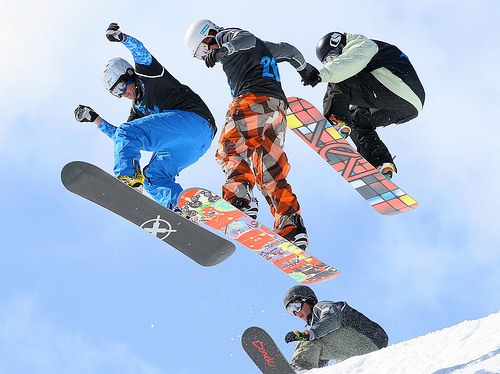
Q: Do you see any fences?
A: No, there are no fences.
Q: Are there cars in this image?
A: No, there are no cars.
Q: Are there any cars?
A: No, there are no cars.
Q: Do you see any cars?
A: No, there are no cars.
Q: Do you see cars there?
A: No, there are no cars.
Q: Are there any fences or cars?
A: No, there are no cars or fences.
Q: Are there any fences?
A: No, there are no fences.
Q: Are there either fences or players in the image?
A: No, there are no fences or players.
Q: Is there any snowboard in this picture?
A: Yes, there is a snowboard.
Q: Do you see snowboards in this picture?
A: Yes, there is a snowboard.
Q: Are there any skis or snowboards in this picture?
A: Yes, there is a snowboard.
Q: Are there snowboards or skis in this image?
A: Yes, there is a snowboard.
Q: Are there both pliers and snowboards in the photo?
A: No, there is a snowboard but no pliers.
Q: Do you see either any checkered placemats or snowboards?
A: Yes, there is a checkered snowboard.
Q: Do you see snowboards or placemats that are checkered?
A: Yes, the snowboard is checkered.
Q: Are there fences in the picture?
A: No, there are no fences.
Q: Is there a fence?
A: No, there are no fences.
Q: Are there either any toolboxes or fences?
A: No, there are no fences or toolboxes.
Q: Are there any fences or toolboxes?
A: No, there are no fences or toolboxes.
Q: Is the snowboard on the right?
A: Yes, the snowboard is on the right of the image.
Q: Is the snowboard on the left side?
A: No, the snowboard is on the right of the image.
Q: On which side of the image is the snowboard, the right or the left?
A: The snowboard is on the right of the image.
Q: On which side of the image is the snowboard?
A: The snowboard is on the right of the image.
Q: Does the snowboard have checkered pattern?
A: Yes, the snowboard is checkered.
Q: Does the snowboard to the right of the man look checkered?
A: Yes, the snowboard is checkered.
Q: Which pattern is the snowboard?
A: The snowboard is checkered.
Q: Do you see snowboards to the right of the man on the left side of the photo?
A: Yes, there is a snowboard to the right of the man.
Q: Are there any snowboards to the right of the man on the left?
A: Yes, there is a snowboard to the right of the man.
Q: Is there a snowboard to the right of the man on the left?
A: Yes, there is a snowboard to the right of the man.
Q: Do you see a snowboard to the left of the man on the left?
A: No, the snowboard is to the right of the man.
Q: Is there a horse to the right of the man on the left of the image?
A: No, there is a snowboard to the right of the man.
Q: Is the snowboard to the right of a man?
A: Yes, the snowboard is to the right of a man.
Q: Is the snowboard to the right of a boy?
A: No, the snowboard is to the right of a man.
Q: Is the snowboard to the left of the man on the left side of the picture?
A: No, the snowboard is to the right of the man.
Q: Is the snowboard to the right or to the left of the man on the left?
A: The snowboard is to the right of the man.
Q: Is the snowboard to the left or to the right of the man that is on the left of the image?
A: The snowboard is to the right of the man.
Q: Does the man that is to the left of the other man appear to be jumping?
A: Yes, the man is jumping.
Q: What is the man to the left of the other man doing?
A: The man is jumping.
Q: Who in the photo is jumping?
A: The man is jumping.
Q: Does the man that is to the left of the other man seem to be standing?
A: No, the man is jumping.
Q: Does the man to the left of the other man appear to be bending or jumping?
A: The man is jumping.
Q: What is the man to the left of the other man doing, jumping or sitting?
A: The man is jumping.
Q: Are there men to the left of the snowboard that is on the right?
A: Yes, there is a man to the left of the snowboard.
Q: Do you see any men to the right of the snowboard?
A: No, the man is to the left of the snowboard.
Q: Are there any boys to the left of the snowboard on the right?
A: No, there is a man to the left of the snow board.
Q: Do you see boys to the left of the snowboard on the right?
A: No, there is a man to the left of the snow board.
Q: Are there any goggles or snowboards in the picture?
A: Yes, there are goggles.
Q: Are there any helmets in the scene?
A: Yes, there is a helmet.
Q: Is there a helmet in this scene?
A: Yes, there is a helmet.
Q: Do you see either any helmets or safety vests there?
A: Yes, there is a helmet.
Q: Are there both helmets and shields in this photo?
A: No, there is a helmet but no shields.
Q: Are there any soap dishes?
A: No, there are no soap dishes.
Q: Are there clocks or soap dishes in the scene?
A: No, there are no soap dishes or clocks.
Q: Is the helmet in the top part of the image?
A: Yes, the helmet is in the top of the image.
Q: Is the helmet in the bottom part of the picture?
A: No, the helmet is in the top of the image.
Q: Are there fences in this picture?
A: No, there are no fences.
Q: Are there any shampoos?
A: No, there are no shampoos.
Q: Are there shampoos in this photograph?
A: No, there are no shampoos.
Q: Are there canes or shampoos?
A: No, there are no shampoos or canes.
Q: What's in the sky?
A: The clouds are in the sky.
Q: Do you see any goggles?
A: Yes, there are goggles.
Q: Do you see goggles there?
A: Yes, there are goggles.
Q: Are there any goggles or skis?
A: Yes, there are goggles.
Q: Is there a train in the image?
A: No, there are no trains.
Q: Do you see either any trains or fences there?
A: No, there are no trains or fences.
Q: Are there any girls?
A: No, there are no girls.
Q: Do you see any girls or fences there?
A: No, there are no girls or fences.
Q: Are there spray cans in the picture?
A: No, there are no spray cans.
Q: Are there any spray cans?
A: No, there are no spray cans.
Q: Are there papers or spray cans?
A: No, there are no spray cans or papers.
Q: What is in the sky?
A: The clouds are in the sky.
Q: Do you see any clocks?
A: No, there are no clocks.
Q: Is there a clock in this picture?
A: No, there are no clocks.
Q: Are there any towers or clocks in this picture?
A: No, there are no clocks or towers.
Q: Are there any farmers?
A: No, there are no farmers.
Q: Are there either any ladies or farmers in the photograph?
A: No, there are no farmers or ladies.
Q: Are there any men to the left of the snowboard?
A: Yes, there is a man to the left of the snowboard.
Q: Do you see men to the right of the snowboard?
A: No, the man is to the left of the snowboard.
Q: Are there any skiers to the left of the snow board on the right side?
A: No, there is a man to the left of the snowboard.